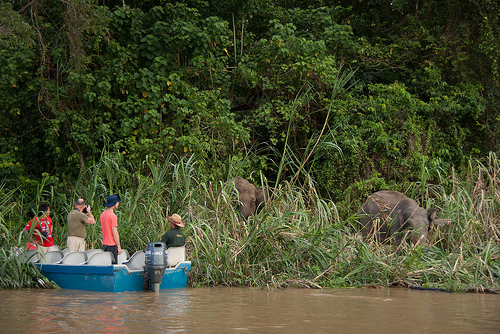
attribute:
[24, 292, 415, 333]
water — brown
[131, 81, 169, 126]
leaves — yellow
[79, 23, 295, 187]
tree — green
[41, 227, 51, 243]
camera — black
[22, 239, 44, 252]
hands — folded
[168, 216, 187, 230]
hat — brown, straw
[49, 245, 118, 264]
seats — white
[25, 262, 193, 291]
boat — blue, small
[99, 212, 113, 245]
shirt — orange, salmon, red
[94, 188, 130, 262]
man — young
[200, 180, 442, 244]
elephants — eating, gray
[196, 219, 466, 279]
grass — tall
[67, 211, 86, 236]
shirt — brown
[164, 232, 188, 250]
shirt — green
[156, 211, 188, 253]
man — sitting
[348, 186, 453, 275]
elephant — hiding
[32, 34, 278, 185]
trees — tall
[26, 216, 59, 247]
shirt — red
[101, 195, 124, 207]
hat — blue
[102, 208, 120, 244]
shirt — pink